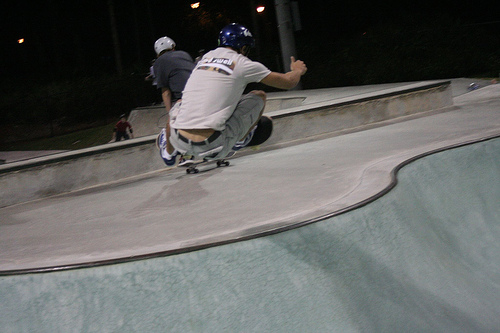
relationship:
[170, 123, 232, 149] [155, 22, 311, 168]
belt on skateboarder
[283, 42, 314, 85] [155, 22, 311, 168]
hand of skateboarder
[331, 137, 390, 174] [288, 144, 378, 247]
curves on surface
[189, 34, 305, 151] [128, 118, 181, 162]
skateboarder at bottom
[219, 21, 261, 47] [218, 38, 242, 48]
helmet on head